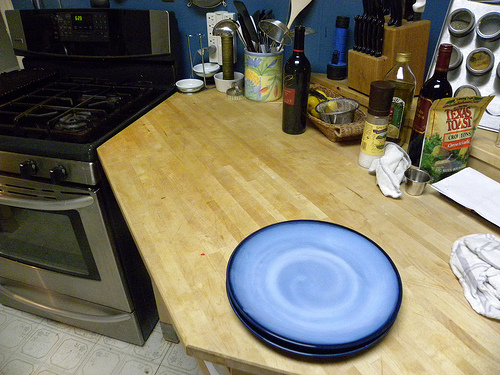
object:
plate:
[224, 219, 403, 352]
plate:
[225, 278, 392, 362]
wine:
[280, 26, 312, 136]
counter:
[95, 84, 500, 375]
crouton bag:
[418, 95, 498, 186]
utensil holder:
[242, 47, 285, 104]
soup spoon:
[212, 18, 250, 51]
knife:
[375, 18, 386, 58]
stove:
[1, 7, 183, 349]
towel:
[366, 140, 412, 201]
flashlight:
[325, 13, 352, 80]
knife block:
[346, 12, 432, 100]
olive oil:
[381, 51, 417, 148]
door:
[0, 169, 136, 316]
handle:
[0, 190, 95, 212]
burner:
[0, 74, 155, 136]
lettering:
[444, 104, 474, 131]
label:
[283, 85, 296, 106]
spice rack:
[420, 1, 500, 135]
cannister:
[464, 46, 495, 76]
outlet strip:
[204, 11, 238, 66]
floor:
[0, 302, 204, 375]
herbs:
[469, 51, 492, 70]